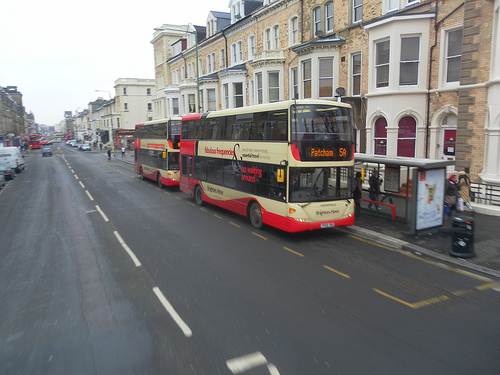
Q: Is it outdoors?
A: Yes, it is outdoors.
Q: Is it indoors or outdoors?
A: It is outdoors.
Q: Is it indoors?
A: No, it is outdoors.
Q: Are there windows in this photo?
A: Yes, there are windows.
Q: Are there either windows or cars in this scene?
A: Yes, there are windows.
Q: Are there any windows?
A: Yes, there are windows.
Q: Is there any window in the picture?
A: Yes, there are windows.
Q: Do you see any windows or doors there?
A: Yes, there are windows.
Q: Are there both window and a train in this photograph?
A: No, there are windows but no trains.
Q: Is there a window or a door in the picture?
A: Yes, there are windows.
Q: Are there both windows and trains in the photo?
A: No, there are windows but no trains.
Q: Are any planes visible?
A: No, there are no planes.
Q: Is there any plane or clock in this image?
A: No, there are no airplanes or clocks.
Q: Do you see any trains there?
A: No, there are no trains.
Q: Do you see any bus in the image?
A: Yes, there is a bus.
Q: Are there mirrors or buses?
A: Yes, there is a bus.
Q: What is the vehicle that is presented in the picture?
A: The vehicle is a bus.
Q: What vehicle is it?
A: The vehicle is a bus.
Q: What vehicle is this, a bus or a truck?
A: That is a bus.